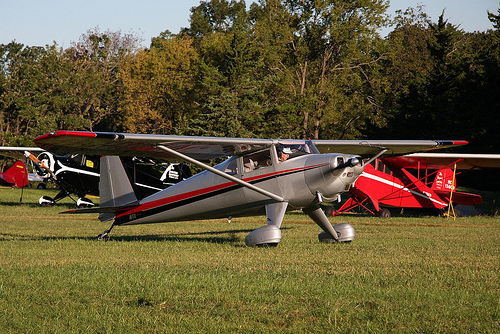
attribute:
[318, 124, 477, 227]
plane — red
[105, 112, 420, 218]
plane — black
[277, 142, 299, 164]
pilot — female, ready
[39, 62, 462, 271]
plane — silver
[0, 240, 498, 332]
grass — short, brown, green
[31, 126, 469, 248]
white plane — black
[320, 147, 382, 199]
propeller — spinning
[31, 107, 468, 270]
aircraft — fixed wing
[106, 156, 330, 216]
line — red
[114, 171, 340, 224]
line — black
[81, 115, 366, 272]
plane — silver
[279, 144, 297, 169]
pilot — starting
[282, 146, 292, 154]
cap — white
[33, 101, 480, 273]
airplane — small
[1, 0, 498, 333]
field — private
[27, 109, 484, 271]
plane — silver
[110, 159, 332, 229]
stripes — black, red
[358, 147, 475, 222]
plane — red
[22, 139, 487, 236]
airplane — silver, black, red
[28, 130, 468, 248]
airplane — single engine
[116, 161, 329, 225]
stripe — red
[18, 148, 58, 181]
propeller — orange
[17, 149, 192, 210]
plane — black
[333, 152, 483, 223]
airplane — red and white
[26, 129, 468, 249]
plane — gray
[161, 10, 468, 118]
tree — big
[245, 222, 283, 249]
front wheel — gray